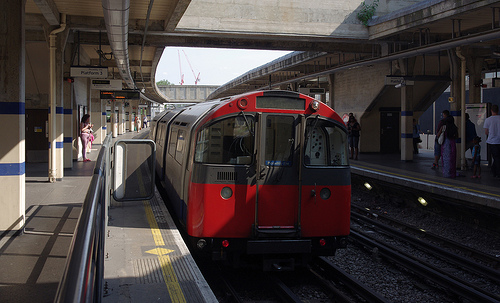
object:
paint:
[141, 245, 176, 258]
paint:
[153, 188, 222, 302]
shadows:
[1, 199, 83, 299]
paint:
[185, 89, 353, 239]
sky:
[153, 46, 298, 85]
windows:
[193, 112, 261, 169]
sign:
[68, 63, 111, 79]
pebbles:
[321, 244, 461, 303]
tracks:
[349, 229, 499, 303]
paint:
[0, 101, 28, 115]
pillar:
[0, 0, 30, 232]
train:
[148, 87, 352, 263]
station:
[0, 0, 195, 303]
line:
[141, 198, 171, 249]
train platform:
[0, 34, 500, 300]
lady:
[78, 112, 97, 163]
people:
[433, 110, 460, 179]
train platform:
[344, 143, 500, 210]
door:
[256, 111, 302, 232]